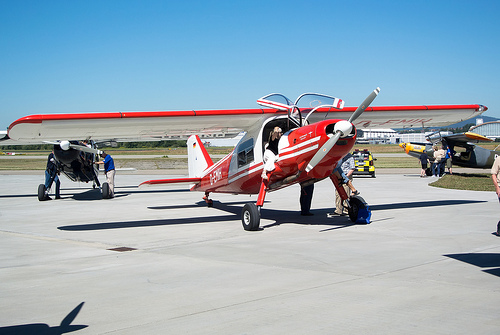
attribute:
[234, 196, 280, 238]
wheel — black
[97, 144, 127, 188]
person — standing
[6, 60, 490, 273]
airplane — red, white, huge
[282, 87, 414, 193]
propeller — grey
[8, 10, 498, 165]
sky — clear, blue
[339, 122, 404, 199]
car — yellow, black, checkered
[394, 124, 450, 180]
propeller — yellow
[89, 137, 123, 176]
shirt — blue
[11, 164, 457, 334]
area — cement, concrete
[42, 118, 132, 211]
plane — black, blue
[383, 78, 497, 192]
airplane — black, gray, yellow, grey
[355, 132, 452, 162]
building — white, large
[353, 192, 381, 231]
wheel piece — blue